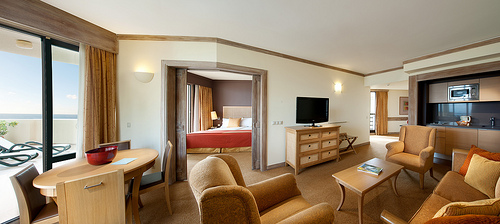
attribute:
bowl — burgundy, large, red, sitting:
[87, 143, 130, 162]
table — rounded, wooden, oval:
[42, 157, 148, 198]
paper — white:
[111, 155, 140, 168]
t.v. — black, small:
[291, 93, 334, 125]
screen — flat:
[304, 104, 328, 117]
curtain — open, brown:
[89, 49, 120, 147]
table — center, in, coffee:
[329, 159, 406, 188]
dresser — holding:
[294, 131, 333, 160]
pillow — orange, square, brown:
[464, 149, 475, 158]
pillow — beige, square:
[467, 163, 496, 192]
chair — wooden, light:
[55, 188, 137, 223]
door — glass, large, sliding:
[43, 43, 88, 161]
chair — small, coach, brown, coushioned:
[207, 165, 280, 224]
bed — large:
[205, 109, 251, 149]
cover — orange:
[195, 127, 248, 149]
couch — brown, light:
[441, 159, 484, 215]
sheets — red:
[221, 132, 262, 149]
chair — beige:
[141, 148, 179, 201]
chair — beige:
[104, 140, 132, 162]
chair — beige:
[11, 164, 60, 214]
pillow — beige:
[221, 114, 256, 132]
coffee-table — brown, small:
[341, 172, 406, 194]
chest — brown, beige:
[292, 127, 337, 172]